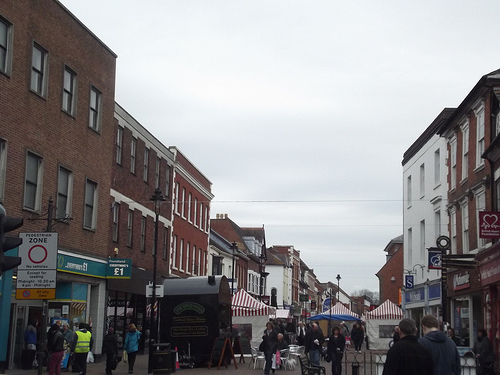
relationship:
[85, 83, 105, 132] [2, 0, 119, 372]
window in building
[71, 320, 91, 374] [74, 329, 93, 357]
man wearing vest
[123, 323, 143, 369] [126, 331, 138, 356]
woman wearing jacket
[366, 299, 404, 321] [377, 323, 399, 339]
tent has window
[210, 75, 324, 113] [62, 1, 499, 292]
cloud in sky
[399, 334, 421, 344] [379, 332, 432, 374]
collar on jacket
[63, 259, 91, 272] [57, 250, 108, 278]
business names on banner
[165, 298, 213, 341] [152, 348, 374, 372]
sign on street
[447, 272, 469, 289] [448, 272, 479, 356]
store sign at entrance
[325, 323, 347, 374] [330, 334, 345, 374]
woman wearing suit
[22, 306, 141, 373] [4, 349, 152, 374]
people on sidewalk